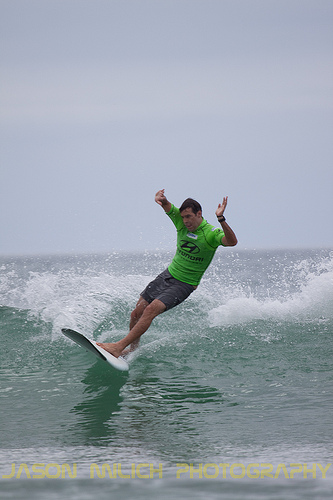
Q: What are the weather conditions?
A: It is cloudy.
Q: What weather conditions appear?
A: It is cloudy.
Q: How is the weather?
A: It is cloudy.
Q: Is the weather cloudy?
A: Yes, it is cloudy.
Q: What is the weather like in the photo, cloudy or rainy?
A: It is cloudy.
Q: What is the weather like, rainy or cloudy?
A: It is cloudy.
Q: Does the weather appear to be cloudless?
A: No, it is cloudy.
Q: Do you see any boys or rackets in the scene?
A: No, there are no boys or rackets.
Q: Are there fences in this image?
A: No, there are no fences.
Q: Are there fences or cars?
A: No, there are no fences or cars.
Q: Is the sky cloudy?
A: Yes, the sky is cloudy.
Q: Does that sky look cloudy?
A: Yes, the sky is cloudy.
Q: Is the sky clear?
A: No, the sky is cloudy.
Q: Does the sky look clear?
A: No, the sky is cloudy.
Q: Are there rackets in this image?
A: No, there are no rackets.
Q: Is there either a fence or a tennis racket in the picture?
A: No, there are no rackets or fences.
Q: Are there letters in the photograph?
A: Yes, there are letters.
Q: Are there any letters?
A: Yes, there are letters.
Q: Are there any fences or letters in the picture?
A: Yes, there are letters.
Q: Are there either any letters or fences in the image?
A: Yes, there are letters.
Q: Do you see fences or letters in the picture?
A: Yes, there are letters.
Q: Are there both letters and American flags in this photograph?
A: No, there are letters but no American flags.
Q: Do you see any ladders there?
A: No, there are no ladders.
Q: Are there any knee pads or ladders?
A: No, there are no ladders or knee pads.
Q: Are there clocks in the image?
A: No, there are no clocks.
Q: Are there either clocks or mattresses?
A: No, there are no clocks or mattresses.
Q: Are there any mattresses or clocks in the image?
A: No, there are no clocks or mattresses.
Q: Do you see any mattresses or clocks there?
A: No, there are no clocks or mattresses.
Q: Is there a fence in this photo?
A: No, there are no fences.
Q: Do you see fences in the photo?
A: No, there are no fences.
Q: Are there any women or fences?
A: No, there are no fences or women.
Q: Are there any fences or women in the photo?
A: No, there are no fences or women.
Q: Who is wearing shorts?
A: The man is wearing shorts.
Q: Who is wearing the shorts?
A: The man is wearing shorts.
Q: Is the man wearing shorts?
A: Yes, the man is wearing shorts.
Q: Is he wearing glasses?
A: No, the man is wearing shorts.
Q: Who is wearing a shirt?
A: The man is wearing a shirt.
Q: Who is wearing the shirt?
A: The man is wearing a shirt.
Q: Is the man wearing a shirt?
A: Yes, the man is wearing a shirt.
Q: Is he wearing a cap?
A: No, the man is wearing a shirt.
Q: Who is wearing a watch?
A: The man is wearing a watch.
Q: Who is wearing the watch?
A: The man is wearing a watch.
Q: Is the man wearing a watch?
A: Yes, the man is wearing a watch.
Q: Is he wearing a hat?
A: No, the man is wearing a watch.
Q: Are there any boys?
A: No, there are no boys.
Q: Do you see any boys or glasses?
A: No, there are no boys or glasses.